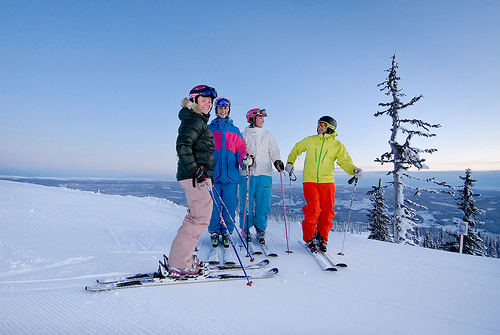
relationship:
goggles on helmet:
[260, 108, 267, 117] [247, 108, 267, 119]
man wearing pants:
[288, 115, 359, 241] [301, 182, 334, 241]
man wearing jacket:
[288, 115, 359, 241] [288, 133, 357, 183]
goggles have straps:
[318, 120, 328, 128] [329, 124, 337, 132]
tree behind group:
[375, 54, 435, 245] [169, 84, 354, 271]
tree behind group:
[447, 168, 487, 252] [169, 84, 354, 271]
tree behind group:
[366, 177, 391, 244] [169, 84, 354, 271]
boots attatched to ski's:
[169, 257, 198, 276] [85, 260, 280, 292]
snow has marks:
[2, 178, 499, 331] [4, 265, 135, 298]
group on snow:
[169, 84, 354, 271] [2, 178, 499, 331]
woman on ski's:
[167, 85, 216, 275] [85, 260, 280, 292]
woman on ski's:
[211, 96, 243, 244] [207, 242, 238, 265]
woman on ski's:
[242, 109, 279, 243] [246, 235, 276, 256]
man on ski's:
[288, 115, 359, 241] [300, 237, 348, 273]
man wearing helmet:
[288, 115, 359, 241] [319, 115, 337, 132]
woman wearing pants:
[211, 96, 243, 244] [212, 181, 237, 233]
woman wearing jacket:
[167, 85, 216, 275] [177, 101, 214, 179]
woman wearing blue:
[211, 96, 243, 244] [210, 118, 242, 236]